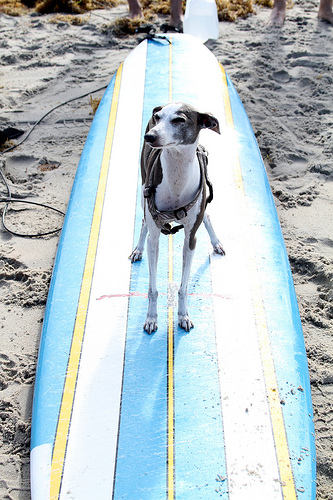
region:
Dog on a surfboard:
[112, 75, 232, 320]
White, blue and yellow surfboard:
[21, 23, 327, 499]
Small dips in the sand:
[4, 416, 33, 464]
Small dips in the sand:
[2, 347, 16, 400]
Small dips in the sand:
[308, 343, 330, 402]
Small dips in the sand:
[0, 449, 13, 480]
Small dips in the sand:
[2, 413, 18, 439]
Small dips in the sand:
[7, 318, 33, 360]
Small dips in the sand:
[10, 254, 38, 312]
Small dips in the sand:
[276, 166, 317, 213]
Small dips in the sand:
[286, 208, 315, 251]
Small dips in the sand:
[297, 247, 323, 293]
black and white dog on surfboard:
[127, 98, 226, 334]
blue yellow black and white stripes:
[21, 346, 295, 498]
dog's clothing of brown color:
[138, 117, 209, 223]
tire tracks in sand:
[4, 113, 94, 141]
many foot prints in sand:
[241, 42, 332, 96]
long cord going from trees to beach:
[0, 76, 117, 239]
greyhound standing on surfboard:
[120, 103, 223, 333]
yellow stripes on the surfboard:
[52, 30, 298, 499]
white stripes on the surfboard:
[60, 30, 281, 499]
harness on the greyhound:
[142, 122, 219, 229]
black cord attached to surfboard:
[1, 31, 166, 236]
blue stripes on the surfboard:
[37, 33, 311, 499]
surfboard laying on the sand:
[31, 30, 318, 499]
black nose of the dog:
[143, 131, 154, 142]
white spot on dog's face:
[149, 106, 178, 138]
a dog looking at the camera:
[104, 94, 232, 343]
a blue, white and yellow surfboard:
[42, 24, 306, 486]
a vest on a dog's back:
[130, 141, 223, 249]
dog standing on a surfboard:
[29, 90, 315, 499]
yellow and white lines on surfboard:
[53, 59, 123, 499]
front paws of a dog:
[141, 293, 193, 336]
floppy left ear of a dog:
[196, 108, 220, 132]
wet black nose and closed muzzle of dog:
[143, 128, 165, 147]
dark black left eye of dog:
[165, 115, 187, 128]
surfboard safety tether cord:
[3, 80, 108, 238]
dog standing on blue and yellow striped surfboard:
[28, 31, 317, 497]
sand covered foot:
[262, 1, 288, 31]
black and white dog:
[128, 100, 225, 334]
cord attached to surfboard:
[0, 74, 107, 236]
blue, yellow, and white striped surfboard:
[29, 35, 316, 497]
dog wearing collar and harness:
[128, 100, 227, 334]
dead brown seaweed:
[0, 0, 127, 17]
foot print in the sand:
[0, 269, 35, 303]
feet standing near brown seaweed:
[112, 0, 298, 32]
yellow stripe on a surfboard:
[49, 61, 122, 498]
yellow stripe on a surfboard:
[168, 34, 172, 497]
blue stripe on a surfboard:
[30, 69, 118, 499]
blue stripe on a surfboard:
[170, 33, 231, 499]